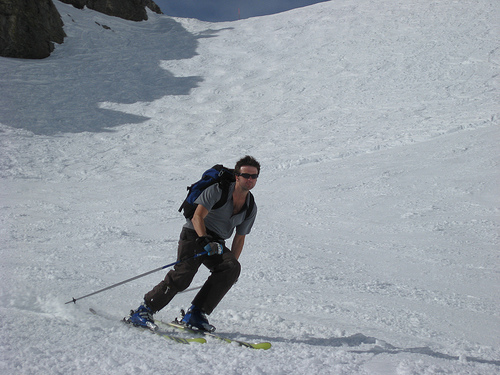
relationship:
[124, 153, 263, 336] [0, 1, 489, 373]
man going down slope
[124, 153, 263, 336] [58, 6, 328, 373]
man skiing down hill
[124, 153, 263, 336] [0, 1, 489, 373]
man skiing down slope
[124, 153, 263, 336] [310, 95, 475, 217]
man skiing down snow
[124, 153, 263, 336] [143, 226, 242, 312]
man wearing pants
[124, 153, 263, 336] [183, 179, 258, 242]
man wearing pullover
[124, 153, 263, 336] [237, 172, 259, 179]
man wearing goggles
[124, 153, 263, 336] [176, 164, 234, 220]
man wearing back pack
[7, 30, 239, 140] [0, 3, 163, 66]
shadows are of pine trees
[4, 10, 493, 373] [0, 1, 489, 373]
tracts are on slope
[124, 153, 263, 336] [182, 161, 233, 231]
man wearing backpack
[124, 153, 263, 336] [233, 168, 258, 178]
man wearing goggles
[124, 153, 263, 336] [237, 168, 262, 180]
man wearing goggles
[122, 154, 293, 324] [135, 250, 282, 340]
man wearing pants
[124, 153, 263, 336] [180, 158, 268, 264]
man wearing shirt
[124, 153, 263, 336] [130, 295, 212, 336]
man wearing shoes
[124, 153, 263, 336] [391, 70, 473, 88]
man skiing through snow